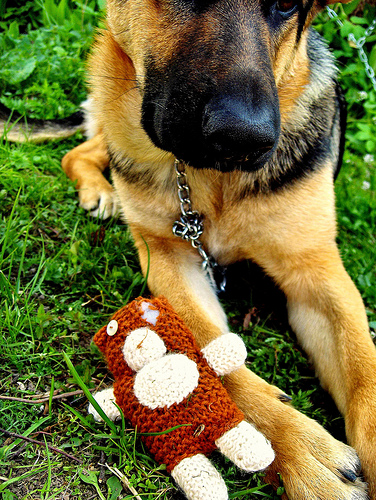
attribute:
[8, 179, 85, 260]
grass — green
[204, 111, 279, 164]
nose — black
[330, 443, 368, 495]
toenail — black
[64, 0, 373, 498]
german shepard — German 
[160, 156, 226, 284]
chain — silver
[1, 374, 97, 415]
sticks — small , wooden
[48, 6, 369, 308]
dog — brown, black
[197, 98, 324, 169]
nose — black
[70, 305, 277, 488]
yarn — brown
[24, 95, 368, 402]
yard — grassy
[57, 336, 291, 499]
toys — brown and white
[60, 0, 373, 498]
dog — brown, white, black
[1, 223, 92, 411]
grass — green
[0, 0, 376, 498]
yard — grassy